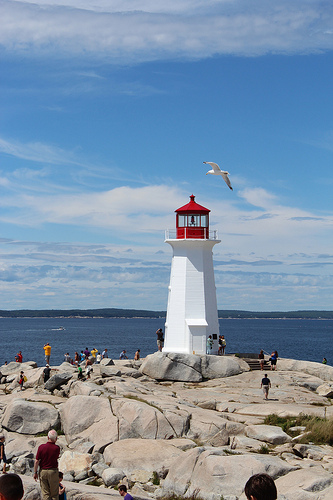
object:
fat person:
[15, 350, 23, 363]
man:
[156, 328, 164, 351]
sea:
[0, 316, 331, 362]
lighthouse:
[161, 193, 221, 352]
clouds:
[0, 0, 333, 307]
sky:
[0, 1, 332, 308]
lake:
[1, 315, 331, 364]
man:
[34, 428, 64, 498]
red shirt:
[35, 444, 60, 470]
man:
[260, 373, 272, 400]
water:
[2, 316, 332, 369]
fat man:
[43, 343, 51, 364]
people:
[17, 370, 27, 391]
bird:
[202, 161, 233, 192]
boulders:
[1, 353, 333, 499]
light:
[190, 216, 195, 227]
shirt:
[44, 345, 52, 355]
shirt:
[261, 378, 270, 386]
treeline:
[0, 307, 165, 317]